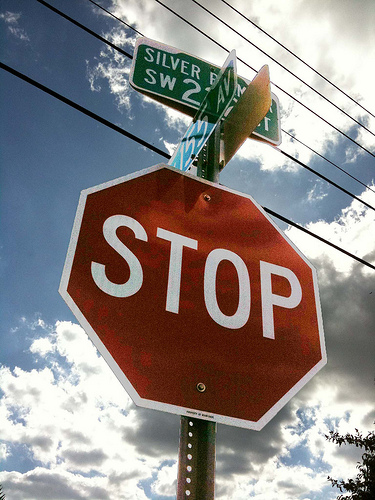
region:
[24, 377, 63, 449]
white clouds in blue sky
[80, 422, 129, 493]
white clouds in blue sky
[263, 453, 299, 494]
white clouds in blue sky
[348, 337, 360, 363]
white clouds in blue sky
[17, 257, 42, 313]
white clouds in blue sky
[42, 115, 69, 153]
white clouds in blue sky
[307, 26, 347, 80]
white clouds in blue sky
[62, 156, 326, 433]
red and white stop sign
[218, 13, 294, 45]
white clouds in blue sky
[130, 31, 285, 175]
white and green street sign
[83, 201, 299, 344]
white lettering on red background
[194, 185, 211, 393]
bolts holding stop sign to pole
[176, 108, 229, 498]
green pole signs are attached to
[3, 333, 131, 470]
clouds backlit by sunlight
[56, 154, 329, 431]
white edges of stop sign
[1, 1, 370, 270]
black power lines above signs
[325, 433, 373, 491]
tree branches and leaves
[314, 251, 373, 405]
gray clouds beside sign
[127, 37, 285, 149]
green sign with white border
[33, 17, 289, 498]
street signs on the pole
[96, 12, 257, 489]
street signs on a metal pole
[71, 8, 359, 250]
green streets sign on a pole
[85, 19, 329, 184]
green signs on a metal pole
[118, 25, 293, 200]
green street signs on a metal pole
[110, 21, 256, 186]
green signs on a pole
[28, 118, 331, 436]
a stop sign on a pole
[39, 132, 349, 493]
a stop sign on a metal pole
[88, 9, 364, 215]
a pole with signs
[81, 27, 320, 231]
a pole with street signs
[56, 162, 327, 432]
the red STOP sign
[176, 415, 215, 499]
the pole holding up the STOP sign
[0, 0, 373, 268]
the power lines in the sky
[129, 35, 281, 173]
the green street signs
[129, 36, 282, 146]
the top street sign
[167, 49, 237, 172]
the bottom street sign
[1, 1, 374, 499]
the white clouds in the sky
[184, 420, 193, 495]
the holes in the pole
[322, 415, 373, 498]
the leaves on the tree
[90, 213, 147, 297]
the "S" on the STOP sign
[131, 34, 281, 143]
a green street sign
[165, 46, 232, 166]
a green street sign to 155th avenue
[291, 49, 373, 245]
telephone lines on the poles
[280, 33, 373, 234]
power lines on the poles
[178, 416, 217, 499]
the steel sign post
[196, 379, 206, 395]
the mounting bolt for the stop sign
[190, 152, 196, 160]
the mounting sign for the street sign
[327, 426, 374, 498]
trees along the street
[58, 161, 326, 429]
metal stop sign on the street corner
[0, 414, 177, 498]
grey clouds in the sky